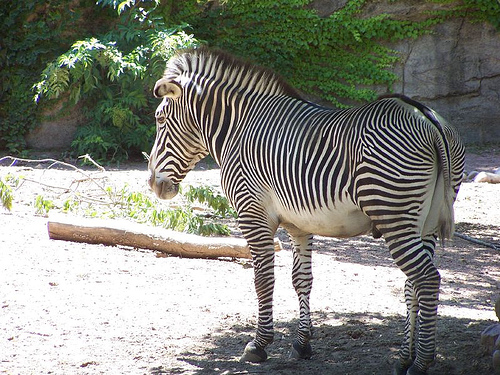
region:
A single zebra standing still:
[132, 38, 479, 373]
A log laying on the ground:
[38, 214, 311, 271]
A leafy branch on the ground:
[6, 148, 271, 233]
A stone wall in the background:
[273, 11, 498, 137]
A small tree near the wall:
[46, 9, 177, 146]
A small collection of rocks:
[444, 166, 493, 189]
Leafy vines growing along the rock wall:
[1, 5, 427, 163]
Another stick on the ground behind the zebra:
[441, 222, 493, 253]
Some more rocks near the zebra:
[473, 280, 498, 372]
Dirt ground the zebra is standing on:
[21, 224, 498, 364]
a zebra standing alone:
[119, 56, 450, 363]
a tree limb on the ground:
[26, 214, 281, 256]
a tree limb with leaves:
[2, 181, 224, 222]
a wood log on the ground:
[26, 220, 253, 261]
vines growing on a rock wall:
[299, 19, 461, 73]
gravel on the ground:
[13, 289, 210, 371]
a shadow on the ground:
[356, 304, 488, 374]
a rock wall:
[357, 13, 488, 97]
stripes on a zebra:
[245, 123, 381, 179]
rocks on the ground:
[466, 159, 498, 211]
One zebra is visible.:
[141, 38, 488, 366]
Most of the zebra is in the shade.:
[151, 8, 498, 371]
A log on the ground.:
[28, 205, 288, 272]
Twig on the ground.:
[5, 138, 169, 229]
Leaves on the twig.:
[109, 185, 236, 240]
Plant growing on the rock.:
[221, 3, 398, 115]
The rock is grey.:
[380, 35, 498, 144]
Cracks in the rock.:
[400, 48, 499, 110]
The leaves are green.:
[48, 0, 203, 144]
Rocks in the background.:
[446, 156, 498, 190]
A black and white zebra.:
[141, 50, 447, 374]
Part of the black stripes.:
[272, 114, 327, 174]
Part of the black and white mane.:
[190, 50, 251, 80]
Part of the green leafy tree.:
[59, 46, 116, 87]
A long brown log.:
[46, 210, 281, 262]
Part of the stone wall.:
[431, 49, 493, 81]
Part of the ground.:
[62, 273, 147, 304]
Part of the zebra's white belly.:
[308, 216, 354, 233]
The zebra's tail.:
[434, 124, 455, 246]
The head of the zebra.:
[145, 49, 207, 201]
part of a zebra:
[420, 306, 430, 336]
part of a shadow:
[327, 347, 342, 371]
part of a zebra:
[308, 213, 325, 240]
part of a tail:
[444, 220, 463, 228]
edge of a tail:
[443, 222, 453, 233]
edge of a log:
[186, 253, 207, 280]